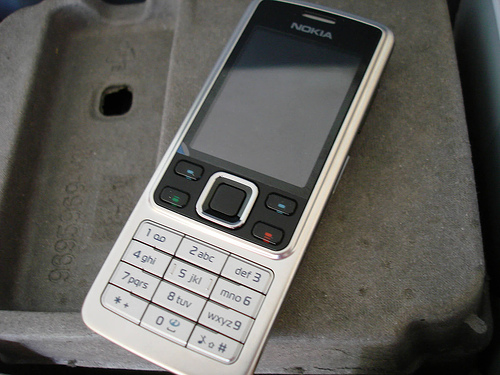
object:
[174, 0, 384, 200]
screen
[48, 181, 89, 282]
number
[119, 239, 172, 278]
buttons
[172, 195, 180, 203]
line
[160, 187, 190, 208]
button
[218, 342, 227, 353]
pound symbol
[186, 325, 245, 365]
pound button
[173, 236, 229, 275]
button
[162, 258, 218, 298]
button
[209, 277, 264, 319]
button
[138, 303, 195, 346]
button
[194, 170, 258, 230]
button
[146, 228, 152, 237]
number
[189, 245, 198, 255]
number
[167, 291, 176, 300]
number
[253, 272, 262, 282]
number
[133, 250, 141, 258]
number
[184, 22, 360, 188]
display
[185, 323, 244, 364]
button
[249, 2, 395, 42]
top part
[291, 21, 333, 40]
writing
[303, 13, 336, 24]
speaker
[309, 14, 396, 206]
screen edge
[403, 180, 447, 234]
stone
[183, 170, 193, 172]
blue line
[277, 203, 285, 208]
blue line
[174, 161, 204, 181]
button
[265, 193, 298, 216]
button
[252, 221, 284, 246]
button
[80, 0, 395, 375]
cell phone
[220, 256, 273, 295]
button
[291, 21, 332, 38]
logo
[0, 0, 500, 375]
sink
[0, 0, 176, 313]
object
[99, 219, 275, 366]
keypad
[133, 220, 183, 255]
button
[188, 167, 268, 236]
outline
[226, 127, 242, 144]
part